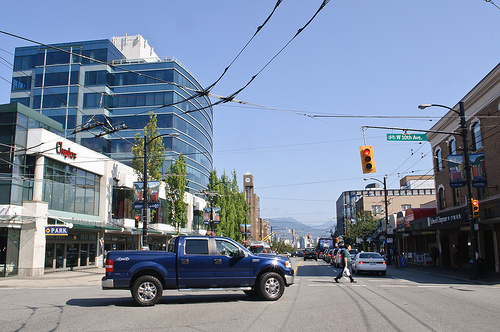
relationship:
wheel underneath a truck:
[258, 271, 285, 302] [100, 234, 298, 310]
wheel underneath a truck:
[131, 275, 163, 307] [100, 234, 298, 310]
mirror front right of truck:
[232, 245, 248, 261] [100, 234, 298, 310]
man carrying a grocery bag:
[331, 243, 356, 287] [342, 266, 352, 279]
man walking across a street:
[331, 243, 356, 287] [164, 249, 455, 331]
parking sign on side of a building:
[46, 224, 71, 237] [0, 113, 108, 281]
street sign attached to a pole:
[389, 132, 429, 143] [361, 124, 465, 134]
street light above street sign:
[416, 100, 434, 110] [389, 132, 429, 143]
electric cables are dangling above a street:
[52, 48, 325, 139] [164, 249, 455, 331]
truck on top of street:
[100, 234, 298, 310] [164, 249, 455, 331]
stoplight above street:
[362, 144, 376, 173] [164, 249, 455, 331]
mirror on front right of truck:
[232, 245, 248, 261] [100, 234, 298, 310]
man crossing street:
[331, 243, 356, 287] [164, 249, 455, 331]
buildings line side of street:
[327, 90, 497, 273] [164, 249, 455, 331]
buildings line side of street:
[4, 35, 267, 270] [164, 249, 455, 331]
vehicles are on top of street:
[295, 237, 387, 272] [164, 249, 455, 331]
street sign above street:
[389, 132, 429, 143] [164, 249, 455, 331]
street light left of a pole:
[416, 100, 434, 110] [450, 101, 483, 282]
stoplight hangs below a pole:
[362, 144, 376, 173] [361, 124, 465, 134]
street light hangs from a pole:
[471, 200, 480, 218] [450, 101, 483, 282]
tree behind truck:
[166, 153, 191, 241] [100, 234, 298, 310]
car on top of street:
[349, 251, 389, 277] [164, 249, 455, 331]